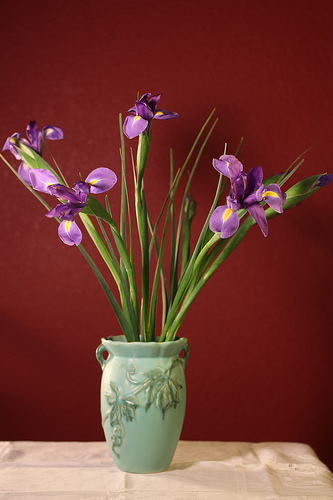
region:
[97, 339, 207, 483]
a green vase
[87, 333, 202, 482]
a green vase with design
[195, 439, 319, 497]
a tan table cloth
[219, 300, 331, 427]
a red wall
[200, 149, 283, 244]
a purple flower bloom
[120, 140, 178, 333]
a green flower stem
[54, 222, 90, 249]
a purple flower petal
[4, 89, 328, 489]
bouquet of purple flowers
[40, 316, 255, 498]
a flower vase sitting on a table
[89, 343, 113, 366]
handles on flower vase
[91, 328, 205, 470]
a green flower vase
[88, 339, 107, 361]
green handle on vase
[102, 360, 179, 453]
floral design on vase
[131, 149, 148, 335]
green flower stem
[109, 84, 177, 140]
a purple flower bud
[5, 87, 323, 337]
a bouquet of flowers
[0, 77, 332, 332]
a bouquet of purple flowers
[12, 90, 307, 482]
a flower vase sitting on table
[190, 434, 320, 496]
a brown tablecloth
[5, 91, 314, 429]
a bouquet of purple flowers on red background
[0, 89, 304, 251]
The flower pedals are purple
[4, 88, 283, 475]
Flowers are in a vase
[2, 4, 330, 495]
Photo was taken indoors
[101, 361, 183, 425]
Vase has leaf designs on it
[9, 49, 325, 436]
Flower is in front of a red wall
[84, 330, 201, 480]
The flower vase is light green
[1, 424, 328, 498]
Vase is on a white table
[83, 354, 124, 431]
Light is reflecting off the vase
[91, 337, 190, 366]
Flower vase has small handles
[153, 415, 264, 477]
Flower vase is casting a shadow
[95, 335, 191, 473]
green decorative porcelain vase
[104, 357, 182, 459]
green leaves on on decorative vase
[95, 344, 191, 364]
two small handles on vase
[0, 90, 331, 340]
purple flowers on long green stems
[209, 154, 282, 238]
purple and yellow petals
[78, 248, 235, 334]
green stems on purple flowers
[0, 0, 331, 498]
purple flowers on display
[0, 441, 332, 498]
white tablecloth cover table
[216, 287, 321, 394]
burgundy wall behind flower arrangement in a vase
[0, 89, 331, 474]
purple and yellow flower arrangement in a porcelain vase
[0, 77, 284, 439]
purple flowers with long stems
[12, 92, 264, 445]
flowers that are in a vase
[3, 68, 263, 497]
flowers on a table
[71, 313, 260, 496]
vase on a table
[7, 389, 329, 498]
a white table cloth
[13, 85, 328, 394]
a red wall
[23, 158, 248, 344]
long flower stems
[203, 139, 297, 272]
a fully bloomed purple flower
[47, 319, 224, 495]
a blue vase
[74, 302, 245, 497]
a vase with handles